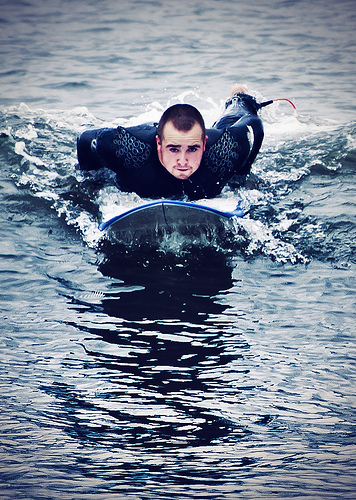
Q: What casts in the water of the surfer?
A: Shadow.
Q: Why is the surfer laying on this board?
A: Waiting.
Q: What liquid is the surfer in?
A: Water.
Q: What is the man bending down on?
A: Surfboard.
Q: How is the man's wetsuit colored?
A: Black.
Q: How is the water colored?
A: Blue.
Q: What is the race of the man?
A: Caucasian.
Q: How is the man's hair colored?
A: Brown.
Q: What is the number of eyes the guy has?
A: Two.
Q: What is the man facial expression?
A: Stern.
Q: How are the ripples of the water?
A: Blue.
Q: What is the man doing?
A: Swimming on a surfboard.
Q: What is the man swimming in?
A: Water.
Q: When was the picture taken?
A: During the day.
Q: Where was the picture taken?
A: In the water.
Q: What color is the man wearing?
A: Black.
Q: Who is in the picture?
A: A man.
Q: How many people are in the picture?
A: One.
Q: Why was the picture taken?
A: To capture the man in the water.